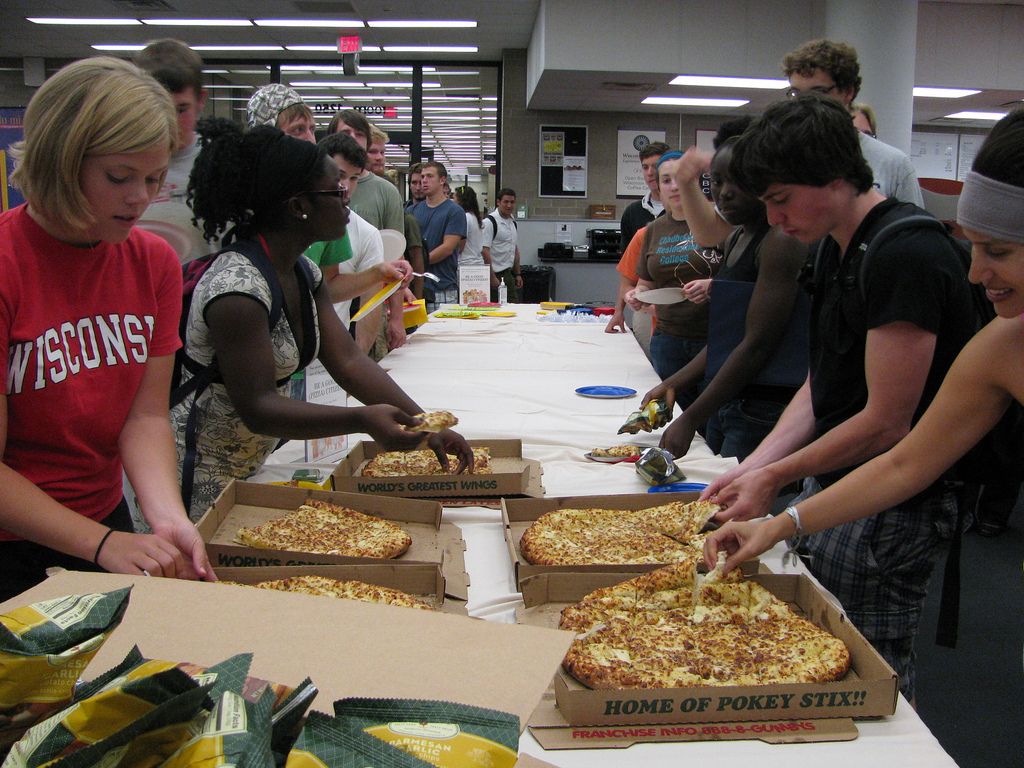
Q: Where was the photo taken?
A: Party.